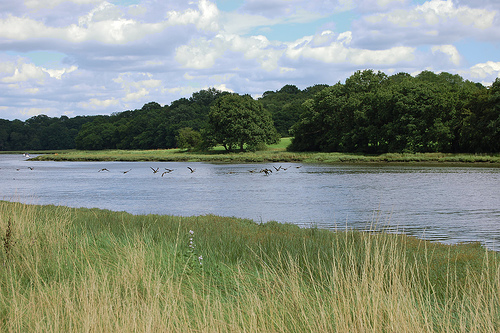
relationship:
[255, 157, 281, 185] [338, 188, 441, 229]
bird in water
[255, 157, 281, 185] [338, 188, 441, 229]
bird on water